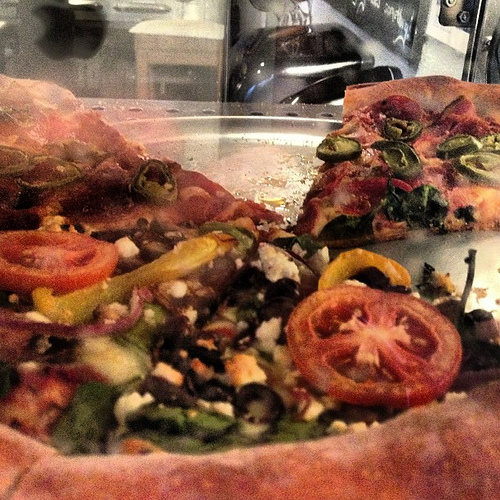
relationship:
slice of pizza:
[0, 218, 275, 497] [0, 71, 498, 500]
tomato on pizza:
[0, 227, 120, 295] [0, 71, 498, 500]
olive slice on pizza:
[264, 276, 304, 304] [0, 71, 498, 500]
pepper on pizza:
[30, 233, 221, 326] [0, 71, 498, 500]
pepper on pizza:
[13, 153, 81, 191] [0, 71, 498, 500]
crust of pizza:
[343, 71, 499, 126] [0, 71, 498, 500]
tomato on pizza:
[287, 282, 462, 405] [0, 71, 498, 500]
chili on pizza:
[315, 135, 364, 162] [0, 71, 498, 500]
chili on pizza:
[381, 116, 421, 142] [0, 71, 498, 500]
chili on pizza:
[438, 132, 483, 161] [0, 71, 498, 500]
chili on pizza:
[456, 151, 499, 189] [0, 71, 498, 500]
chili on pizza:
[2, 145, 30, 177] [0, 71, 498, 500]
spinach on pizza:
[382, 175, 450, 224] [0, 71, 498, 500]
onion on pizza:
[0, 284, 151, 334] [0, 71, 498, 500]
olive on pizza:
[146, 374, 193, 408] [0, 71, 498, 500]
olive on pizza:
[255, 297, 297, 326] [0, 71, 498, 500]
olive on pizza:
[184, 365, 235, 401] [0, 71, 498, 500]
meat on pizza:
[343, 175, 414, 211] [0, 71, 498, 500]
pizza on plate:
[0, 71, 498, 500] [77, 96, 500, 332]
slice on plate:
[0, 75, 287, 227] [77, 96, 500, 332]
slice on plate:
[0, 218, 275, 497] [77, 96, 500, 332]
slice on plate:
[3, 230, 499, 499] [77, 96, 500, 332]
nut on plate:
[456, 9, 472, 25] [436, 0, 476, 27]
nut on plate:
[444, 0, 456, 8] [436, 0, 476, 27]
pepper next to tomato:
[13, 153, 81, 191] [0, 227, 120, 295]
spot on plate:
[164, 108, 180, 116] [77, 96, 500, 332]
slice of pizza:
[0, 75, 287, 227] [0, 71, 498, 500]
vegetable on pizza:
[315, 246, 412, 291] [0, 71, 498, 500]